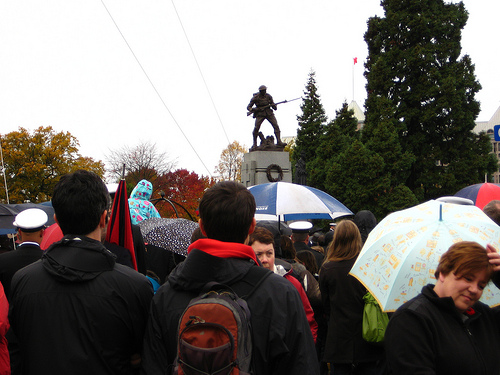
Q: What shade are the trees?
A: Green.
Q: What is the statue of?
A: A soldier.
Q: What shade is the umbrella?
A: Blue and white.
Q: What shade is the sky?
A: Light grey.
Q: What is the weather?
A: Rainy and cold.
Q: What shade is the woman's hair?
A: Red.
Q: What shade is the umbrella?
A: Blue and white.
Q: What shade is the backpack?
A: Orange and black.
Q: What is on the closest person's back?
A: Backpack.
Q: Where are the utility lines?
A: Overhead.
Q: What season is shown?
A: Autumn.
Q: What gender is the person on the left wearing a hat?
A: Male.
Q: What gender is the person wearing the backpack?
A: Male.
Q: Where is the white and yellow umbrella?
A: Behind the closest woman.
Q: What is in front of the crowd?
A: Statue.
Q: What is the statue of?
A: Soldier.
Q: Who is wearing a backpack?
A: Man with red scarf.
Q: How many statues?
A: 1.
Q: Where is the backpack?
A: On the guy.